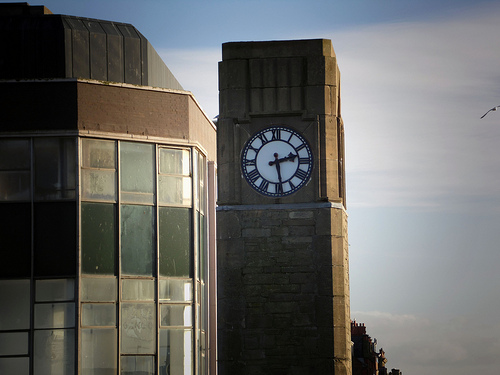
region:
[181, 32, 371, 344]
a tower is located next to the building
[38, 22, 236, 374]
the building is long in lenght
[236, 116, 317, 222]
the clock is located high on the tower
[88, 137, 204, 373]
the building wall is made of glasses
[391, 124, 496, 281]
the sky is coverd of clouds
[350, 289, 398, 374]
trees are seen at the background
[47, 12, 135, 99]
the wall isgrayin color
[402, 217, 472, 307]
the sky is dark blure incolor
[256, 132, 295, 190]
the clock is numberd in black color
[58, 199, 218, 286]
the windows are tinted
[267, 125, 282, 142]
roman numeral on clock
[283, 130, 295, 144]
roman numeral on clock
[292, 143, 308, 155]
roman numeral on clock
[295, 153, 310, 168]
roman numeral on clock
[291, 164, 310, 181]
roman numeral on clock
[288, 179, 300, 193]
roman numeral on clock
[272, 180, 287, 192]
roman numeral on clock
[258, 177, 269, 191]
roman numeral on clock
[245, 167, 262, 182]
roman numeral on clock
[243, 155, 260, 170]
roman numeral on clock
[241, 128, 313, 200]
the tower has a clock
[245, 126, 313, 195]
the clock has a white clockface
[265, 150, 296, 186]
the dials are made of metal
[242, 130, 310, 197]
the clock has roman numerals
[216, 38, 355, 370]
the tower is made of concrete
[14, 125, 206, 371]
a wall of windows is on the building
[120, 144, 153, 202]
the window is made of glass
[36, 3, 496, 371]
the sky is blue in color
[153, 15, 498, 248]
soft clouds are in the sky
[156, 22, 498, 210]
the clouds are greyish in color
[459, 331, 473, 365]
Life size bear on the side of a building.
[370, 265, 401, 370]
Life size bear on the side of a building.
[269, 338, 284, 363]
Life size bear on the side of a building.